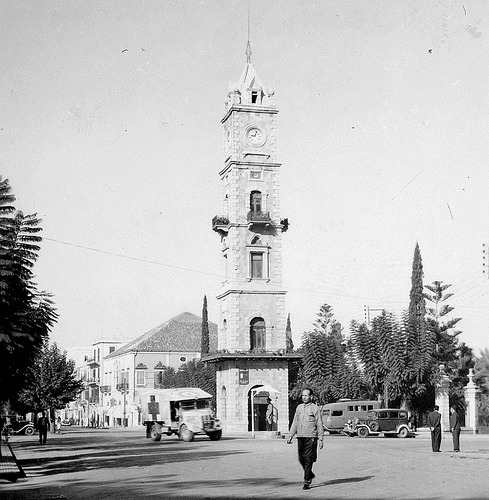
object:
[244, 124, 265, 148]
round clock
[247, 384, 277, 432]
doorway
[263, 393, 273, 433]
guard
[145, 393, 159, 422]
cross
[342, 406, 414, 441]
car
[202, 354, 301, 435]
story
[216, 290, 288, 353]
story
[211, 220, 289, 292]
story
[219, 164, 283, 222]
story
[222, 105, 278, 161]
story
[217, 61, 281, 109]
story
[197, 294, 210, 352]
trees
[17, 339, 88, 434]
tree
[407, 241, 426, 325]
tree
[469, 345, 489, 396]
tree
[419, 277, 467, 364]
tree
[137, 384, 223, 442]
medical truck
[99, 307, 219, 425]
buildings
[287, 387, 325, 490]
person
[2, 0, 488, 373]
sky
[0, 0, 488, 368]
clouds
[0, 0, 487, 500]
downtown scene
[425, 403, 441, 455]
men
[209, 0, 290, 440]
building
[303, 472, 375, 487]
shadows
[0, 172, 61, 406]
trees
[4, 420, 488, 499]
ground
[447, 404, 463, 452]
man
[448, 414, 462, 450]
suit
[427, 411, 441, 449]
suit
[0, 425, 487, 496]
road